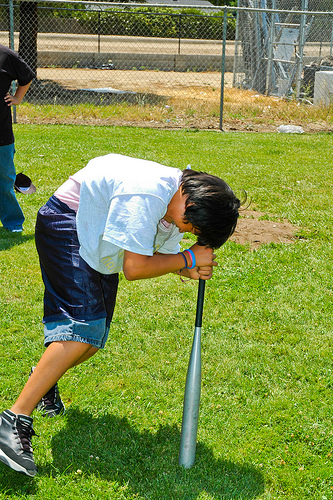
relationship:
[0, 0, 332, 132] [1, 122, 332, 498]
fence borders ball park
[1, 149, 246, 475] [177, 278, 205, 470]
boy holding baseball bat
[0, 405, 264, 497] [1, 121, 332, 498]
shadow on grass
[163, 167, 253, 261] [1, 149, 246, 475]
hair on boy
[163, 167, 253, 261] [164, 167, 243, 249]
hair on head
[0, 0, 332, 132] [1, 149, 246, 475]
fence behind boy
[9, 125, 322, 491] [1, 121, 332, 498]
field has grass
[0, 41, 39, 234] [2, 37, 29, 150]
person wearing shirt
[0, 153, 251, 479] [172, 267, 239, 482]
boy spinning on bat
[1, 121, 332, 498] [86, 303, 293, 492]
grass playing field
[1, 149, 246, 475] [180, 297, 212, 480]
boy spinning head on bat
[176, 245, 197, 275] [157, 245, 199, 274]
bracelets on a wrist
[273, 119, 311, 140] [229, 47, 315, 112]
snow melting near fence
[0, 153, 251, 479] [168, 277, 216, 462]
boy holding bat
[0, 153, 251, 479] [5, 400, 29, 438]
boy not wearing socks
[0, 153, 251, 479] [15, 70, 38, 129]
boy has witness